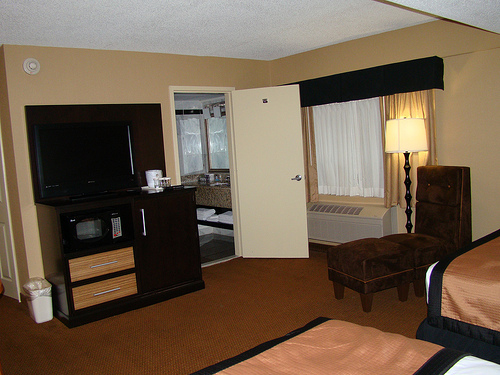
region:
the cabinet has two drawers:
[56, 190, 169, 317]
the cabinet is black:
[62, 170, 212, 330]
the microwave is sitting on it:
[54, 208, 142, 265]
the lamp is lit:
[368, 100, 428, 167]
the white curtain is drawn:
[317, 102, 404, 205]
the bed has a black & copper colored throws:
[337, 339, 471, 369]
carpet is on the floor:
[116, 300, 256, 344]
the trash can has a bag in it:
[23, 278, 60, 326]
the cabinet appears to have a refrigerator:
[136, 200, 239, 291]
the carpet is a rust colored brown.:
[123, 307, 223, 346]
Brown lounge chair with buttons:
[321, 160, 473, 309]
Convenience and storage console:
[31, 177, 215, 332]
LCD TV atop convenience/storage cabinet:
[22, 99, 170, 206]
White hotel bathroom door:
[220, 78, 315, 263]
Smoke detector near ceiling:
[18, 36, 52, 80]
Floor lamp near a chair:
[380, 111, 437, 247]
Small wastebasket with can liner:
[14, 273, 65, 328]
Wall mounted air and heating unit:
[302, 196, 398, 253]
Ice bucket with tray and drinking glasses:
[140, 163, 175, 199]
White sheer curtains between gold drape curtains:
[300, 87, 439, 209]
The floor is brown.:
[101, 311, 198, 368]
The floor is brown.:
[171, 304, 226, 371]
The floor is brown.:
[171, 257, 248, 328]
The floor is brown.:
[148, 332, 163, 362]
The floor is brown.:
[124, 260, 212, 367]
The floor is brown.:
[147, 337, 182, 371]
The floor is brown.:
[144, 275, 245, 373]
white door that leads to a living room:
[227, 79, 319, 269]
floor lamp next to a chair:
[371, 106, 436, 233]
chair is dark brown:
[388, 159, 479, 277]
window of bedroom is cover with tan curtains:
[297, 47, 432, 214]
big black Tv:
[28, 111, 148, 207]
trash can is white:
[19, 273, 56, 328]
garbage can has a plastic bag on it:
[17, 270, 64, 333]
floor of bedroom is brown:
[51, 279, 416, 345]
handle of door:
[287, 171, 304, 187]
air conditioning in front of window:
[304, 199, 391, 248]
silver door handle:
[287, 170, 303, 185]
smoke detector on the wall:
[17, 54, 47, 75]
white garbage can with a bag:
[20, 268, 55, 328]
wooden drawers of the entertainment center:
[61, 243, 141, 313]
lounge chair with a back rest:
[325, 149, 485, 301]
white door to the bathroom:
[225, 79, 317, 260]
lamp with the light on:
[380, 94, 424, 270]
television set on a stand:
[37, 106, 136, 216]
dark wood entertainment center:
[27, 91, 212, 321]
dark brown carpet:
[205, 266, 319, 321]